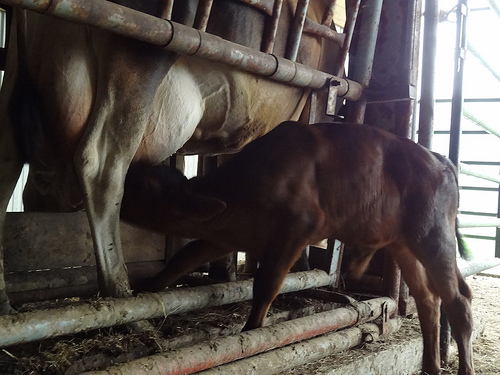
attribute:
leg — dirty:
[410, 232, 470, 374]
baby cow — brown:
[169, 104, 496, 330]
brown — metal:
[197, 32, 316, 82]